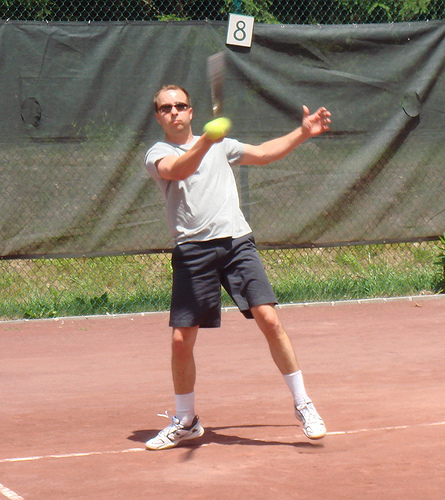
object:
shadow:
[126, 419, 321, 455]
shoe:
[290, 396, 328, 443]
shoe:
[140, 410, 206, 453]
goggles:
[159, 101, 191, 118]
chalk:
[0, 290, 445, 500]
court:
[3, 1, 444, 498]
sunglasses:
[157, 98, 195, 115]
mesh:
[1, 3, 26, 23]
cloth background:
[1, 19, 444, 259]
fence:
[2, 0, 445, 253]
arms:
[226, 120, 303, 168]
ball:
[204, 114, 232, 143]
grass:
[269, 242, 445, 297]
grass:
[0, 259, 165, 317]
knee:
[254, 307, 282, 330]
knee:
[173, 334, 194, 349]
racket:
[206, 51, 226, 117]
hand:
[298, 102, 331, 136]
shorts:
[159, 232, 293, 330]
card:
[224, 12, 256, 50]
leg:
[143, 259, 206, 454]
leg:
[223, 250, 329, 443]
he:
[142, 81, 329, 451]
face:
[157, 91, 189, 130]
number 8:
[232, 19, 247, 41]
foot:
[295, 406, 328, 441]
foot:
[142, 415, 206, 452]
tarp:
[0, 20, 442, 257]